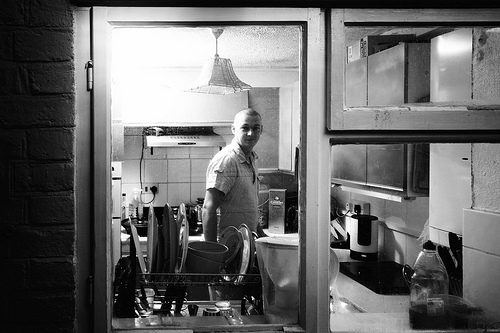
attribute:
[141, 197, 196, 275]
plate — dark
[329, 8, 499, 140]
cabinet — set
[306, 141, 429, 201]
cabinet — set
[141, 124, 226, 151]
vent hood — white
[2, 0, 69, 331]
wall — stone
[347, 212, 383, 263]
cylinder — white 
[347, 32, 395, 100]
panes — glass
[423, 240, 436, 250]
cap — black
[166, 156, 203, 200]
tiles — in photo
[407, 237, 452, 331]
bottle — clear, plastic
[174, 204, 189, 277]
plate — light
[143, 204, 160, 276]
plate — light